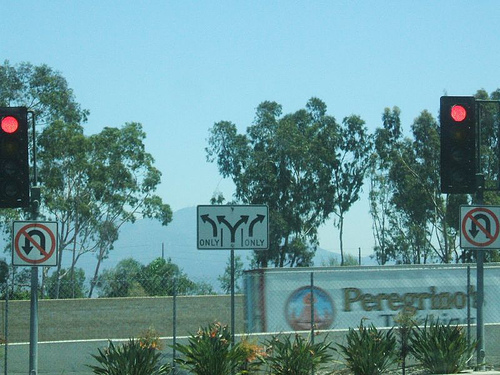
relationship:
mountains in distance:
[151, 209, 197, 240] [105, 195, 211, 270]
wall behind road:
[94, 233, 186, 315] [0, 325, 500, 375]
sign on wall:
[195, 198, 275, 254] [94, 233, 186, 315]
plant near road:
[101, 223, 170, 277] [61, 317, 147, 375]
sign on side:
[195, 198, 275, 254] [98, 289, 205, 371]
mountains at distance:
[151, 209, 197, 240] [105, 195, 211, 270]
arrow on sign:
[247, 198, 274, 241] [194, 203, 274, 250]